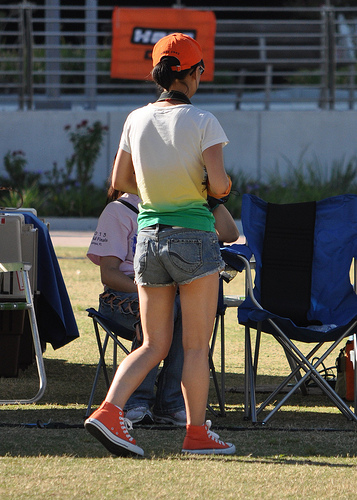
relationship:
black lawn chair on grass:
[70, 252, 229, 397] [136, 455, 345, 499]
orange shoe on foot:
[82, 394, 146, 452] [87, 398, 246, 459]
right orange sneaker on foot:
[178, 412, 238, 470] [87, 398, 246, 459]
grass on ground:
[10, 457, 134, 486] [4, 404, 344, 481]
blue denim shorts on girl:
[134, 220, 221, 280] [82, 35, 238, 461]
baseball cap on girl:
[143, 30, 213, 86] [82, 35, 238, 461]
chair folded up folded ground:
[1, 204, 65, 419] [2, 181, 344, 495]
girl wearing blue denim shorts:
[82, 35, 238, 461] [134, 220, 221, 280]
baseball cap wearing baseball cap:
[150, 30, 206, 67] [150, 30, 206, 67]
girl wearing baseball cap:
[82, 35, 238, 461] [150, 30, 206, 67]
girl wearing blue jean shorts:
[82, 35, 238, 461] [119, 219, 236, 286]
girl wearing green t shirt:
[82, 35, 238, 461] [104, 108, 256, 234]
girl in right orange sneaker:
[82, 35, 238, 461] [185, 412, 237, 458]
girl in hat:
[82, 35, 238, 461] [143, 32, 204, 74]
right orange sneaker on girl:
[185, 412, 237, 458] [82, 35, 238, 461]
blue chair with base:
[219, 193, 353, 394] [243, 330, 346, 416]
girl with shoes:
[82, 35, 238, 461] [81, 397, 236, 457]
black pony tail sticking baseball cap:
[149, 55, 178, 93] [150, 30, 206, 67]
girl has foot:
[82, 35, 238, 461] [181, 435, 238, 456]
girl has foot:
[82, 35, 238, 461] [82, 408, 145, 458]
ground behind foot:
[0, 450, 355, 499] [181, 435, 238, 456]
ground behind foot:
[0, 450, 355, 499] [82, 408, 145, 458]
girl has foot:
[82, 35, 238, 461] [181, 433, 233, 454]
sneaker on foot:
[180, 422, 237, 455] [181, 433, 233, 454]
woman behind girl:
[84, 174, 189, 433] [82, 35, 238, 461]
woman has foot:
[84, 174, 189, 433] [126, 404, 155, 429]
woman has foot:
[84, 174, 189, 433] [157, 406, 188, 426]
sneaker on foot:
[125, 405, 154, 423] [126, 404, 155, 429]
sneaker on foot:
[154, 408, 187, 425] [157, 406, 188, 426]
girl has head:
[82, 35, 238, 461] [148, 30, 203, 96]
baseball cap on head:
[150, 30, 206, 67] [148, 30, 203, 96]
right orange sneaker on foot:
[185, 412, 237, 458] [178, 436, 235, 453]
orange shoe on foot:
[82, 394, 146, 452] [84, 413, 145, 456]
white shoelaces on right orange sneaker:
[203, 418, 244, 449] [185, 412, 237, 458]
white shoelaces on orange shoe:
[117, 410, 156, 458] [82, 394, 146, 452]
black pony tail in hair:
[149, 55, 178, 93] [150, 54, 207, 89]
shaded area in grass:
[10, 346, 353, 459] [0, 244, 356, 499]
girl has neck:
[82, 35, 238, 461] [152, 85, 190, 107]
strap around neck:
[154, 90, 190, 102] [152, 85, 190, 107]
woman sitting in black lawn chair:
[84, 174, 189, 433] [70, 252, 229, 397]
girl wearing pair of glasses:
[82, 35, 238, 461] [190, 55, 209, 80]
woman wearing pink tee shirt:
[84, 174, 189, 433] [89, 185, 137, 279]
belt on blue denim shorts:
[149, 222, 176, 229] [134, 220, 221, 280]